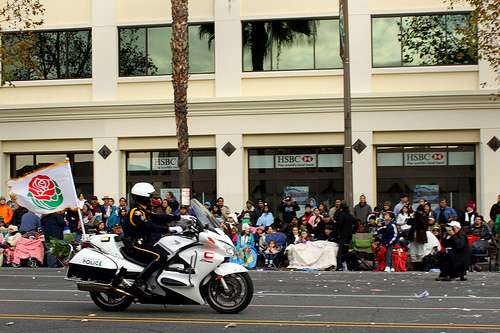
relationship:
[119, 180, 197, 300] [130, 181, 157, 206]
man wearing helmet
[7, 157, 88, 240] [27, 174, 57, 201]
flag has a rose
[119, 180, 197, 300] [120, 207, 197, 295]
man wearing uniform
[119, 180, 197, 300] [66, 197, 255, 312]
man on bike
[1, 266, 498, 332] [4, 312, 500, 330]
road has stripe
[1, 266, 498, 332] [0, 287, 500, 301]
road has stripe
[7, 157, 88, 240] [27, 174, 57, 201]
flag has flower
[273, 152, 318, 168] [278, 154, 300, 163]
sign says hsbc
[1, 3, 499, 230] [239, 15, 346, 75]
building has window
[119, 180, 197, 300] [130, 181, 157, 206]
officer wearing helmet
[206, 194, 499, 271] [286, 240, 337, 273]
people have blanket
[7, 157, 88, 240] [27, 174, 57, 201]
flag has rose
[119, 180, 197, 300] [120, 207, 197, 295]
cop in uniform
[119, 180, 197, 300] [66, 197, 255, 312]
officer riding motorcycle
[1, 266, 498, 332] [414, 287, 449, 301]
road has debris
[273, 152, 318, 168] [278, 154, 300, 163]
sign says hbc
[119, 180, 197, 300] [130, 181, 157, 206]
policeman wearing helmet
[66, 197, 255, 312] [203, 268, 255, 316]
motorcycle has tire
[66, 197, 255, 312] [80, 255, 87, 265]
motorcycle has p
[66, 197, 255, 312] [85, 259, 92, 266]
"motorcycle has o